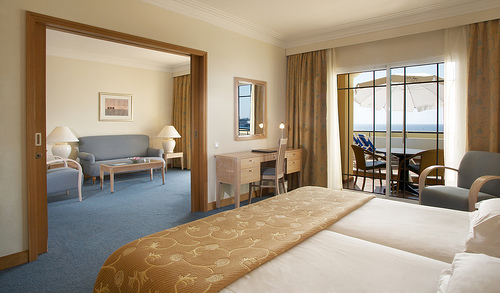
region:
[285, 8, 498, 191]
Large luxurious tan curtains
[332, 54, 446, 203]
Window overlooking a patio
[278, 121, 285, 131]
A lit lightbulb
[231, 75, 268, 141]
A wooden trimmed mirror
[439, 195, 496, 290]
A pile of white pillows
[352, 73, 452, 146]
A white patio umbrella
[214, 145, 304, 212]
A small five drawered desk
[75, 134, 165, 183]
A light blue sofa seat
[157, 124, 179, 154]
A white lamp with a white shade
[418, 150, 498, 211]
A light blue chair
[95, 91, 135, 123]
Painting on the wall in the living room of hotel suite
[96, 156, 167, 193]
Light colored wooden coffee table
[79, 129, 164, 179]
Light blue sofa in a hotel suite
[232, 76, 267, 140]
Mirror with wooden frame in a hotel suite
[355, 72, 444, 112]
White top of a patio umbrella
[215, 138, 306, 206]
Wooden desk and chair in the corner of the room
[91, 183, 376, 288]
Yellow patterned blanket at the foot of a bed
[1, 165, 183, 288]
Blue carpet covering two rooms of a hotel suite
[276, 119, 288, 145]
Turned on desk lamp sitting in the corner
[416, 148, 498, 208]
Light blue chair with wooden arms sitting next to a bed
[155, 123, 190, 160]
a lamp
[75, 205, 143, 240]
the carpet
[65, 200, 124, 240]
the carpet is blue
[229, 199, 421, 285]
the bed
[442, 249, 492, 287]
pillows on the bed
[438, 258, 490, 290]
the pillows are white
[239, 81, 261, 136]
a mirror on the wall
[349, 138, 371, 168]
a chair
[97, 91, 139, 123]
a picture on the wall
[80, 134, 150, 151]
the couch is blue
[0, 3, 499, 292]
room of hotel/motel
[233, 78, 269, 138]
mirror for viewing one's reflection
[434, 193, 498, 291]
four pillows for comfort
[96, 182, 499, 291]
made up bed for sleeping on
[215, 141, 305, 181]
desk with drawers and chair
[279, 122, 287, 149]
small desk lamp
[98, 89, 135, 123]
picture frame for wall art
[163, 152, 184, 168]
end table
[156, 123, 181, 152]
large white lamp with shade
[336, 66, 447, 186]
ocean side view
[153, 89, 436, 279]
this is a hotel suite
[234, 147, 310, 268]
this is a bed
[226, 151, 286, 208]
this is a desk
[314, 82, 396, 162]
this is a window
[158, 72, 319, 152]
this is a mirror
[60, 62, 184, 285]
this is a couch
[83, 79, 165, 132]
this is a painting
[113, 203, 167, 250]
this is blue carpet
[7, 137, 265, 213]
this is a doorway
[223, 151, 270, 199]
the desk is wooden